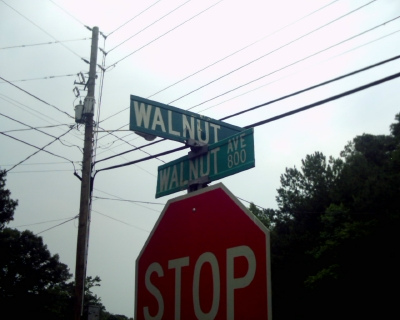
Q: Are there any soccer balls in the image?
A: No, there are no soccer balls.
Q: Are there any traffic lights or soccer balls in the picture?
A: No, there are no soccer balls or traffic lights.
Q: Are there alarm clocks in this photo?
A: No, there are no alarm clocks.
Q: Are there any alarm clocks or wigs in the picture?
A: No, there are no alarm clocks or wigs.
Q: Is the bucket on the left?
A: Yes, the bucket is on the left of the image.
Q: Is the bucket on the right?
A: No, the bucket is on the left of the image.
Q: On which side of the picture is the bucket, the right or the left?
A: The bucket is on the left of the image.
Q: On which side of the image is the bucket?
A: The bucket is on the left of the image.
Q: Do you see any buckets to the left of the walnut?
A: Yes, there is a bucket to the left of the walnut.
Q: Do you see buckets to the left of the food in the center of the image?
A: Yes, there is a bucket to the left of the walnut.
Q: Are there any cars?
A: No, there are no cars.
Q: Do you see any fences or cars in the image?
A: No, there are no cars or fences.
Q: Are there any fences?
A: No, there are no fences.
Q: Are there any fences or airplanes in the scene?
A: No, there are no fences or airplanes.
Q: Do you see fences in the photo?
A: No, there are no fences.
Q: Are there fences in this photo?
A: No, there are no fences.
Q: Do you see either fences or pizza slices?
A: No, there are no fences or pizza slices.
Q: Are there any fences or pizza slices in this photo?
A: No, there are no fences or pizza slices.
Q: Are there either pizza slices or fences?
A: No, there are no fences or pizza slices.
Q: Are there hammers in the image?
A: No, there are no hammers.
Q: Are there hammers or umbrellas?
A: No, there are no hammers or umbrellas.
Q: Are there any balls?
A: No, there are no balls.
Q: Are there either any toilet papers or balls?
A: No, there are no balls or toilet papers.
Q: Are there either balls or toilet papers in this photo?
A: No, there are no balls or toilet papers.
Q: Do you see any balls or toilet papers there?
A: No, there are no balls or toilet papers.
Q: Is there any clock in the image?
A: No, there are no clocks.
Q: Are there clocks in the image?
A: No, there are no clocks.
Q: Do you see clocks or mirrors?
A: No, there are no clocks or mirrors.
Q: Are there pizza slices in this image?
A: No, there are no pizza slices.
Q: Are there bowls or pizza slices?
A: No, there are no pizza slices or bowls.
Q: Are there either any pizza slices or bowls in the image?
A: No, there are no pizza slices or bowls.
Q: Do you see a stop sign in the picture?
A: Yes, there is a stop sign.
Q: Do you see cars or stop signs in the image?
A: Yes, there is a stop sign.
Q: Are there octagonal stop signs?
A: Yes, there is an octagonal stop sign.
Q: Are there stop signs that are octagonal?
A: Yes, there is a stop sign that is octagonal.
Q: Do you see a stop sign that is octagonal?
A: Yes, there is a stop sign that is octagonal.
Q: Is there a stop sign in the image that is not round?
A: Yes, there is a octagonal stop sign.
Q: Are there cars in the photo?
A: No, there are no cars.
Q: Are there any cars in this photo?
A: No, there are no cars.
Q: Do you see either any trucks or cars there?
A: No, there are no cars or trucks.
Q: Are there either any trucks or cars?
A: No, there are no cars or trucks.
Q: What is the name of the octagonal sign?
A: The sign is a stop sign.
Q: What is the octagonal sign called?
A: The sign is a stop sign.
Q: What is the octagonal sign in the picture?
A: The sign is a stop sign.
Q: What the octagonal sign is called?
A: The sign is a stop sign.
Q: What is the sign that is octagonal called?
A: The sign is a stop sign.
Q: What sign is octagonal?
A: The sign is a stop sign.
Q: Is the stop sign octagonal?
A: Yes, the stop sign is octagonal.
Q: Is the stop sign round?
A: No, the stop sign is octagonal.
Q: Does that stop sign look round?
A: No, the stop sign is octagonal.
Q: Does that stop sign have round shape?
A: No, the stop sign is octagonal.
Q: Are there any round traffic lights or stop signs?
A: No, there is a stop sign but it is octagonal.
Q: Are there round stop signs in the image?
A: No, there is a stop sign but it is octagonal.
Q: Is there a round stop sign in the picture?
A: No, there is a stop sign but it is octagonal.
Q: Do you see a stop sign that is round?
A: No, there is a stop sign but it is octagonal.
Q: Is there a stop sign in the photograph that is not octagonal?
A: No, there is a stop sign but it is octagonal.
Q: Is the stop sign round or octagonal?
A: The stop sign is octagonal.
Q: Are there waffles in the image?
A: No, there are no waffles.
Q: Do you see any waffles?
A: No, there are no waffles.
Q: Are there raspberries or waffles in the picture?
A: No, there are no waffles or raspberries.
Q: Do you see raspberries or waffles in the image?
A: No, there are no waffles or raspberries.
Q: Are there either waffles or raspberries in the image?
A: No, there are no waffles or raspberries.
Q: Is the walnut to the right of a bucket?
A: Yes, the walnut is to the right of a bucket.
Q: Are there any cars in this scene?
A: No, there are no cars.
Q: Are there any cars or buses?
A: No, there are no cars or buses.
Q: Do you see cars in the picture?
A: No, there are no cars.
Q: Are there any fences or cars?
A: No, there are no cars or fences.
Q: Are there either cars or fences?
A: No, there are no cars or fences.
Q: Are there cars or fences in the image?
A: No, there are no fences or cars.